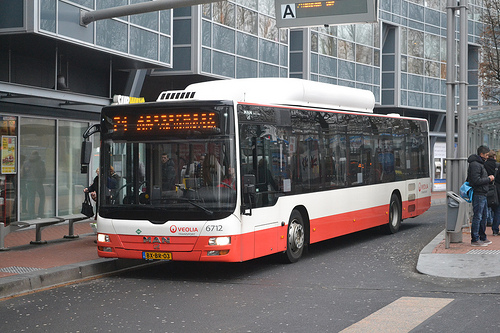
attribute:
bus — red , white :
[100, 77, 435, 271]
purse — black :
[78, 188, 98, 220]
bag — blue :
[457, 182, 471, 199]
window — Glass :
[241, 104, 431, 209]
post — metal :
[434, 0, 485, 260]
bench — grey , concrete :
[57, 211, 87, 241]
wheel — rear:
[381, 184, 406, 232]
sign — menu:
[6, 115, 16, 260]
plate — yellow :
[139, 247, 191, 261]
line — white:
[338, 296, 455, 329]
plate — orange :
[132, 240, 184, 276]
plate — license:
[141, 250, 179, 261]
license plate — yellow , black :
[139, 248, 176, 262]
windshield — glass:
[75, 113, 237, 216]